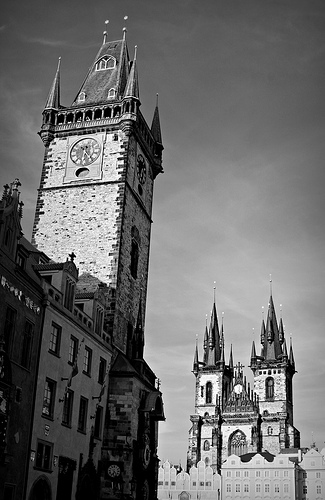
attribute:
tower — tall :
[183, 269, 295, 483]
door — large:
[227, 428, 247, 454]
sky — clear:
[170, 172, 291, 288]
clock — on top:
[231, 383, 243, 396]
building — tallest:
[70, 19, 192, 132]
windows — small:
[224, 470, 291, 497]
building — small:
[212, 441, 322, 498]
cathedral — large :
[157, 265, 320, 498]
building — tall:
[58, 101, 155, 220]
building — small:
[26, 32, 162, 285]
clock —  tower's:
[64, 134, 106, 170]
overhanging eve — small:
[145, 386, 167, 425]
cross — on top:
[230, 361, 247, 378]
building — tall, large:
[186, 268, 300, 471]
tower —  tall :
[30, 14, 162, 355]